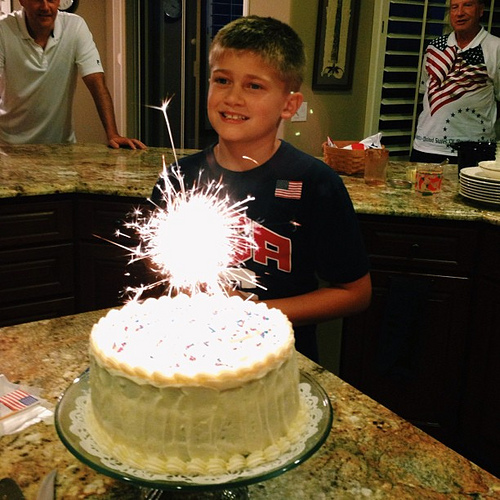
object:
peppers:
[416, 178, 434, 192]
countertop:
[1, 140, 500, 226]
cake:
[91, 294, 298, 470]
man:
[1, 1, 148, 150]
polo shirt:
[1, 8, 104, 145]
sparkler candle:
[88, 92, 270, 318]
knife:
[36, 469, 59, 500]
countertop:
[0, 297, 500, 499]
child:
[145, 12, 372, 363]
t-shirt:
[151, 140, 367, 339]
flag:
[274, 177, 303, 200]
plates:
[459, 164, 500, 204]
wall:
[10, 1, 107, 143]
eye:
[245, 82, 266, 90]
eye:
[213, 76, 233, 86]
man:
[404, 1, 500, 167]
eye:
[463, 3, 474, 8]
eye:
[451, 4, 459, 10]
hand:
[108, 133, 147, 152]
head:
[205, 16, 306, 141]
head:
[21, 1, 61, 27]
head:
[447, 0, 478, 32]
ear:
[280, 93, 304, 121]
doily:
[69, 382, 322, 487]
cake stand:
[54, 366, 334, 500]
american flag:
[1, 388, 36, 419]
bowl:
[479, 159, 500, 178]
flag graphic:
[424, 33, 490, 116]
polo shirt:
[411, 25, 499, 157]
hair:
[207, 17, 303, 94]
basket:
[321, 140, 384, 178]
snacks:
[326, 132, 383, 150]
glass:
[414, 162, 439, 189]